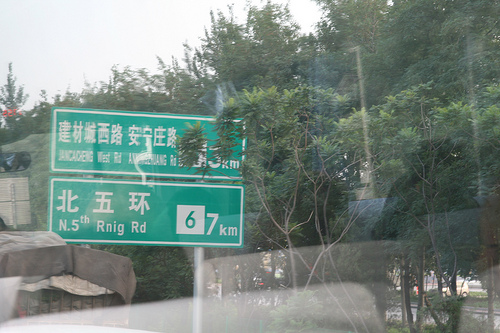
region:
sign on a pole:
[75, 105, 294, 219]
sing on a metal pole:
[41, 83, 289, 213]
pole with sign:
[57, 177, 235, 284]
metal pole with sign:
[44, 166, 264, 291]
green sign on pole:
[57, 151, 282, 312]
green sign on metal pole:
[37, 175, 268, 308]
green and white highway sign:
[49, 106, 240, 248]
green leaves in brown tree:
[344, 91, 389, 124]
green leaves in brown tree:
[367, 87, 405, 117]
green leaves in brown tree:
[246, 74, 277, 101]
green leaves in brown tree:
[286, 164, 362, 223]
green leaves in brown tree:
[367, 41, 408, 95]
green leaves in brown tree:
[431, 59, 453, 94]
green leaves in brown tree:
[364, 140, 427, 200]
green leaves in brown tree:
[370, 16, 399, 48]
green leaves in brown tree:
[409, 41, 437, 80]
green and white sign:
[52, 91, 249, 251]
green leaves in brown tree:
[350, 36, 397, 66]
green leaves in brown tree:
[425, 145, 456, 177]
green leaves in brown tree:
[442, 92, 477, 136]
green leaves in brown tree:
[304, 146, 336, 186]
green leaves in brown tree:
[285, 116, 313, 154]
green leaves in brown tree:
[411, 69, 462, 121]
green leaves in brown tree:
[405, 32, 469, 72]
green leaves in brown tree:
[281, 55, 325, 119]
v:
[298, 162, 326, 174]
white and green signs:
[26, 102, 258, 254]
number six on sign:
[165, 201, 210, 243]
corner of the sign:
[26, 92, 81, 146]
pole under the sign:
[164, 239, 226, 311]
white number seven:
[196, 203, 226, 244]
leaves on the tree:
[257, 77, 372, 153]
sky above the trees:
[36, 9, 147, 54]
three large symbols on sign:
[41, 178, 163, 218]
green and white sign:
[35, 96, 255, 265]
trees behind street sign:
[215, 32, 400, 197]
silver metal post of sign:
[174, 234, 220, 329]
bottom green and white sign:
[28, 163, 253, 263]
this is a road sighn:
[59, 107, 247, 179]